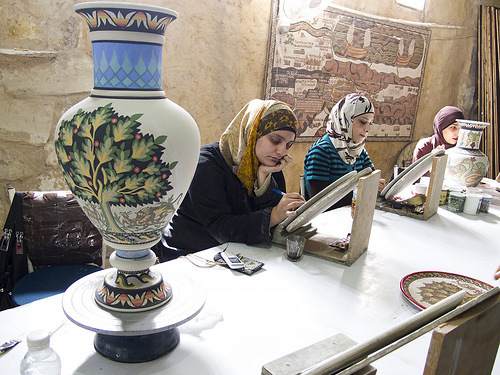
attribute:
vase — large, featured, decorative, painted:
[47, 0, 206, 316]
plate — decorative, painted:
[395, 268, 495, 318]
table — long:
[0, 174, 499, 374]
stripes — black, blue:
[301, 132, 383, 184]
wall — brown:
[2, 1, 500, 241]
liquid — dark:
[289, 251, 307, 260]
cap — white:
[25, 325, 55, 350]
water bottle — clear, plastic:
[17, 328, 63, 374]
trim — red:
[398, 265, 497, 314]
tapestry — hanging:
[254, 2, 433, 152]